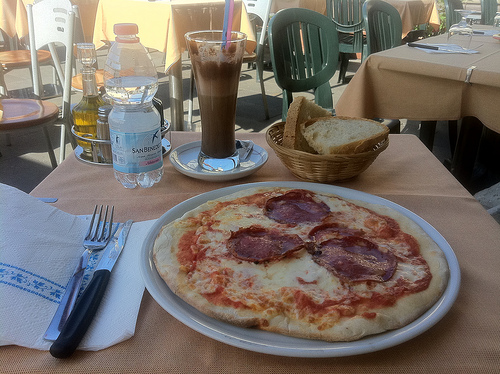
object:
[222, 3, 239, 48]
straw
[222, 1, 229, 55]
straw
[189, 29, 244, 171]
cup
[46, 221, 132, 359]
knife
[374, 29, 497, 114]
table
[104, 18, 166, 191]
bottle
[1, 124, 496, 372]
tablecloth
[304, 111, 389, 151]
bread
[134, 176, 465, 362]
plate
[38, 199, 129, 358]
fork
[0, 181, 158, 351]
napkin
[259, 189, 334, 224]
pepperoni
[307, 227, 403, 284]
pepperoni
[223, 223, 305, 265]
pepperoni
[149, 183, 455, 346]
pizza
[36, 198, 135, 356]
utensils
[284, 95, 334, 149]
bread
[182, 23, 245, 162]
glass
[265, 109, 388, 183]
basket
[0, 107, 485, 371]
table